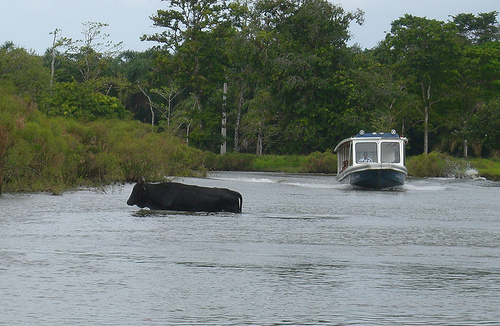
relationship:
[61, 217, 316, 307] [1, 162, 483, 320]
water in creek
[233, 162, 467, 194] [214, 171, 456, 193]
path of waves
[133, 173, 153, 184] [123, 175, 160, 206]
horns on head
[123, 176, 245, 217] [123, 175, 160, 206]
cow has head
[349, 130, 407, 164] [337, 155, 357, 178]
frame on mirrors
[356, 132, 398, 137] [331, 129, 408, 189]
blue top on boat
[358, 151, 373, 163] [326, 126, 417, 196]
man on boat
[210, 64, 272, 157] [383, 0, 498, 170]
trunk on tree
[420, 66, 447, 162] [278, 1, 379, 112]
trunk on tree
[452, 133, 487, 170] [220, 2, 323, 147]
trunk on tree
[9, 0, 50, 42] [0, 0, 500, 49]
clouds in blue sky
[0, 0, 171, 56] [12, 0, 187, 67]
clouds in sky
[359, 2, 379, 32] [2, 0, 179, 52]
clouds in blue sky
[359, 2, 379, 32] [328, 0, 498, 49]
clouds in blue sky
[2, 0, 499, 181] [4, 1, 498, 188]
leaves on trees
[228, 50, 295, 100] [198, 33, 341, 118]
leaves on trees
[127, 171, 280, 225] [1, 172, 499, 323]
cow walking in water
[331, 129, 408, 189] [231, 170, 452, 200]
boat made wake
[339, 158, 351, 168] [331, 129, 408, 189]
people on boat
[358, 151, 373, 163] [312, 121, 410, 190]
man drives boat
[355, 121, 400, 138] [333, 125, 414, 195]
lights on boat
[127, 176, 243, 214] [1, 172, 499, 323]
cow in water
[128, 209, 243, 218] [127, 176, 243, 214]
reflection from cow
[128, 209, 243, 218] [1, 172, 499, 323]
reflection on water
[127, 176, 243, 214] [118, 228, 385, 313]
cow treading through water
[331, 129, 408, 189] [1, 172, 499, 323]
boat driving in water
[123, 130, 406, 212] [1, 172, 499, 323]
boat in water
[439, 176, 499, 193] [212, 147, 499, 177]
wave crashing onto shore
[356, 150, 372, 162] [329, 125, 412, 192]
man driving boat